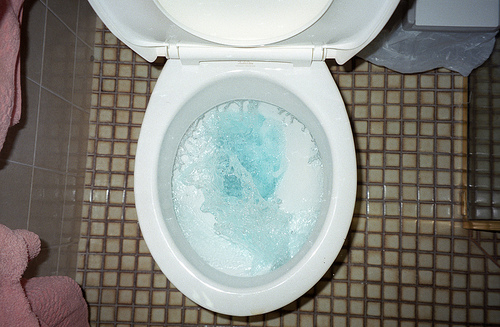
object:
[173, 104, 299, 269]
product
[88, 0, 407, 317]
toilet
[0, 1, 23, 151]
towel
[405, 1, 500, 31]
bin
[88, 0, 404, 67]
seat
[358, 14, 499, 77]
bag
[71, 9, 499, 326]
floor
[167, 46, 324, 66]
hinge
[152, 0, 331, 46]
lid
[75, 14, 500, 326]
tiles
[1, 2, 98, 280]
wall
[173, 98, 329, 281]
water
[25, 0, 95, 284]
reflection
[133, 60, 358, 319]
bowl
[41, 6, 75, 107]
tile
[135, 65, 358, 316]
seat